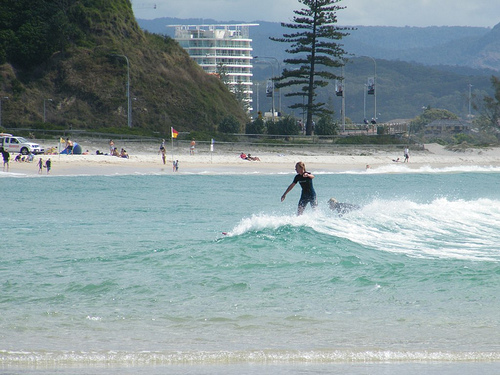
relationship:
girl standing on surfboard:
[280, 162, 318, 217] [220, 226, 238, 237]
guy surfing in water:
[327, 198, 361, 219] [2, 171, 489, 368]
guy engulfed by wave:
[327, 198, 361, 219] [242, 195, 499, 253]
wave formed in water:
[242, 195, 499, 253] [2, 171, 489, 368]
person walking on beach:
[45, 157, 52, 173] [1, 145, 498, 172]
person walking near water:
[45, 157, 52, 173] [2, 171, 489, 368]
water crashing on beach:
[2, 171, 489, 368] [1, 145, 498, 172]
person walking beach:
[45, 159, 53, 171] [11, 132, 484, 175]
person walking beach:
[0, 144, 12, 171] [0, 142, 498, 177]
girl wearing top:
[280, 162, 318, 217] [292, 172, 316, 193]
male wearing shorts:
[157, 137, 177, 167] [58, 146, 78, 154]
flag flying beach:
[172, 129, 179, 139] [0, 142, 498, 177]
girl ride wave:
[280, 162, 318, 217] [244, 200, 485, 258]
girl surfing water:
[280, 162, 318, 217] [343, 241, 423, 288]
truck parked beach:
[0, 133, 44, 155] [1, 134, 498, 174]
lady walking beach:
[157, 138, 183, 172] [12, 141, 489, 173]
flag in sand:
[172, 129, 179, 139] [7, 144, 494, 172]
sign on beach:
[206, 130, 218, 166] [1, 110, 498, 180]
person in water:
[357, 159, 378, 175] [2, 171, 489, 368]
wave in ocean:
[0, 165, 500, 375] [6, 168, 497, 350]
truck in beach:
[1, 131, 41, 156] [0, 142, 498, 177]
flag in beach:
[172, 129, 179, 139] [0, 148, 497, 174]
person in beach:
[37, 154, 42, 172] [0, 136, 499, 177]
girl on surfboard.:
[280, 162, 318, 217] [277, 211, 371, 241]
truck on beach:
[0, 133, 44, 155] [3, 129, 498, 180]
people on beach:
[149, 133, 223, 158] [4, 129, 489, 193]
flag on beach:
[139, 102, 206, 162] [138, 95, 190, 205]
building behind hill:
[169, 21, 261, 125] [1, 1, 249, 135]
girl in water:
[280, 162, 318, 217] [262, 243, 394, 282]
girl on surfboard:
[263, 150, 325, 244] [242, 210, 377, 235]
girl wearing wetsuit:
[280, 162, 318, 217] [293, 173, 322, 203]